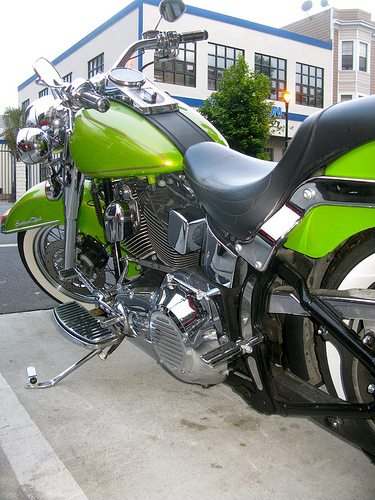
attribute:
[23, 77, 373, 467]
motorcycle — green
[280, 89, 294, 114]
light — street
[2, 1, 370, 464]
motorcycle — green, white, black, silver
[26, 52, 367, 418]
motorcycle — green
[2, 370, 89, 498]
white strip — dirty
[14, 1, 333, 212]
building — blue